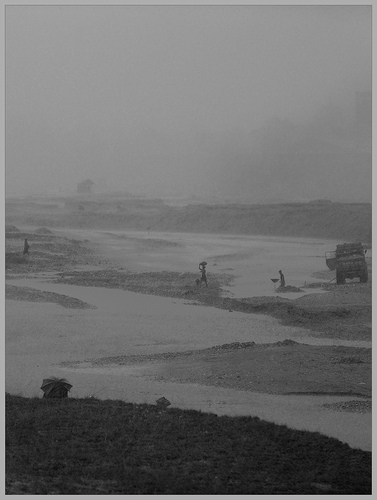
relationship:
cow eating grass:
[113, 401, 193, 444] [36, 350, 326, 487]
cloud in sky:
[1, 2, 373, 180] [6, 6, 375, 205]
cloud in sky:
[1, 2, 373, 180] [15, 33, 361, 245]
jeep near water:
[325, 243, 369, 285] [1, 272, 370, 454]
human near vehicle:
[271, 267, 292, 287] [321, 228, 365, 283]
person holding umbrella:
[194, 261, 215, 291] [38, 368, 77, 396]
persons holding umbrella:
[38, 364, 75, 415] [40, 371, 75, 389]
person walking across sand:
[18, 237, 34, 260] [12, 261, 50, 276]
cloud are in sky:
[1, 2, 373, 180] [6, 6, 375, 205]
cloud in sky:
[158, 29, 223, 80] [6, 6, 375, 205]